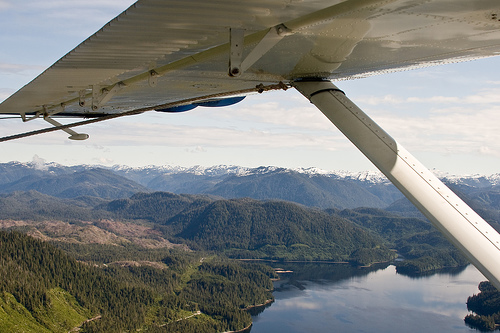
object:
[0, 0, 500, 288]
plane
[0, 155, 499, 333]
mountains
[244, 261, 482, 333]
water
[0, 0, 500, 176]
sky